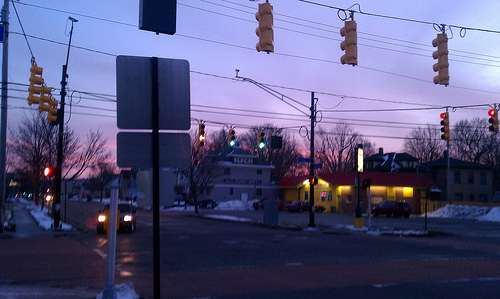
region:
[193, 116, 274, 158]
A row of street lights.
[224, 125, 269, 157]
The lights are green.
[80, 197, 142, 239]
A car makes a turn.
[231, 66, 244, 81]
A traffic camera.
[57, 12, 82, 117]
A camera on a pole.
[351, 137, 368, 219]
The sign is light up.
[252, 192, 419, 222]
Cars in a parking lot.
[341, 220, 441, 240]
Snow on the ground.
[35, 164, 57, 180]
A red hand signal.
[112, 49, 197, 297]
The back of a street sign.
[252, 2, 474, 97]
three yellow painted street lights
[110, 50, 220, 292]
three rectangle street sign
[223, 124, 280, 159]
two green light street lights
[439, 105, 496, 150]
two red light street lights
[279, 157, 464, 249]
yellow and red building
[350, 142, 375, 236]
lighted commercial sign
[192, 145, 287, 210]
large Victorian house with attic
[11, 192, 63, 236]
side walk with snow on the side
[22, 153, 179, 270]
car turning the corner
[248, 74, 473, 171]
pink, gray, and blue sky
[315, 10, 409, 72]
Stop light hanging from wire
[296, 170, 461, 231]
Yellow building with red roof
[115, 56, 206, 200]
Back of street sign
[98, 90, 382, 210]
Pink and blue sun set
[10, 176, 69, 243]
Snow on the sidewalk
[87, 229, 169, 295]
Reflection of lights on street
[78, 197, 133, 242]
Car headlights are on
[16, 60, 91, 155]
Three signal lights hanging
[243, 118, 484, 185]
Trees have no leaves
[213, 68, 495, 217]
Many wires overhead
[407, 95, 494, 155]
traffic lights turned red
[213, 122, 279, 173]
traffic lights turned green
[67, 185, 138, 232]
a car with head lights on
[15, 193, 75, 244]
snow on the side walk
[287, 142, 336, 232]
blue street sign on the corner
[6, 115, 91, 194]
the trees are bare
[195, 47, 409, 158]
wires above the street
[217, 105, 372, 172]
the sky is pinkish red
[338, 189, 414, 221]
a maroon parked car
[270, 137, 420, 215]
a building with a red top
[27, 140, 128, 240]
dusk scene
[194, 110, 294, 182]
three traffic lights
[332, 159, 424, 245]
car parked in front of lit up store front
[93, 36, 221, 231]
street sign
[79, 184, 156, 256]
car with front lights on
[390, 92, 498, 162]
two traffic lights signaling stop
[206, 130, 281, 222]
home behind two green traffic lights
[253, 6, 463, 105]
row of three traffic lights facing street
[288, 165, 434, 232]
store front during evening time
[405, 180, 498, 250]
bank of snow in front of store